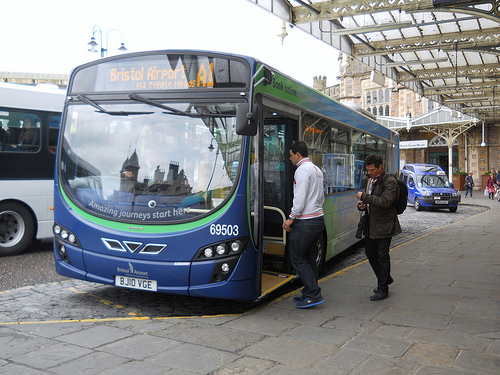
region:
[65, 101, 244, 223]
The front window of the bus.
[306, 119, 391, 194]
The passenger windows of the bus the man is getting on.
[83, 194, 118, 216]
The word Amazing on the window of the bus.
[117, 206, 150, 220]
The word journeys on the window of the bus.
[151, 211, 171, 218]
The word Start on the window of the bus.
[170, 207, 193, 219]
The word Here on the window of the bus.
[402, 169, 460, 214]
The blue car behind the bus.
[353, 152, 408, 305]
man looking at his watch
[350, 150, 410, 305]
man wearing a black backpack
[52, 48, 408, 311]
two men boarding a bus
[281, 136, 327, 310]
man wearing a white jacket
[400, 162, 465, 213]
shiny blue compact vehicle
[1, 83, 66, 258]
black and white transit bus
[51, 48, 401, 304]
blue and white bus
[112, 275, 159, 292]
white and black license plate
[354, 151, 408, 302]
man wearing a brown jacket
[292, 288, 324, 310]
black shoes with blue soles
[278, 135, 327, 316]
man is getting onto bus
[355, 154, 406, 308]
man is wearing a brown jacket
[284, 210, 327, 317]
man is wearing blue jeans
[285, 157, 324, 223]
man is wearing a white sweater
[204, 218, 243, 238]
bus has numbers on it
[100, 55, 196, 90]
bus is going to the airport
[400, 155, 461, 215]
a blue car is behind the bus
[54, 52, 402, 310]
the bus is blue and green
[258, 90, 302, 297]
the door on the bus is open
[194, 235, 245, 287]
the bus has four lights on the front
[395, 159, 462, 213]
a blue van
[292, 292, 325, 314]
a man's tennis shoe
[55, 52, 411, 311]
a long blue bus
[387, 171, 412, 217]
part of a black backpack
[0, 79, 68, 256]
part of a white bus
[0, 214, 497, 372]
a sidewalk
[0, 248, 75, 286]
part of a road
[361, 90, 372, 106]
a window of a building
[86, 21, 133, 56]
part of a lamp light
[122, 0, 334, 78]
a white sky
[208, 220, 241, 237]
The 5 digit number on the bus.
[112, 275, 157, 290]
The license plate of the bus.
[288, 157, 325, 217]
The white and red jacket the man is wearing.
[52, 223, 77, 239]
The 3 left headlights of the bus.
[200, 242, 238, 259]
The 3 right headlights of the bus.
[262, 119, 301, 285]
The open door of the bus.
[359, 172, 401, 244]
The black jacket the man is wearing.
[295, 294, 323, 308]
The blue and black sneakers the man is wearing.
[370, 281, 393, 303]
The black shoes the man is wearing.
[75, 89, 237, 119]
The windshield wipers on the front window of the bus.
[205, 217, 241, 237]
"69503" is written in white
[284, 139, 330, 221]
Man wearing a white sweater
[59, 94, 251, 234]
Front window of a bus